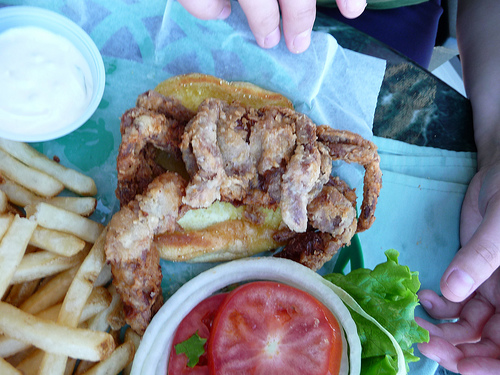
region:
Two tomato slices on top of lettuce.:
[168, 283, 345, 373]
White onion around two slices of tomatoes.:
[127, 255, 404, 372]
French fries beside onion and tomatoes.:
[0, 142, 116, 373]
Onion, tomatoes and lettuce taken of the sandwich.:
[129, 256, 431, 373]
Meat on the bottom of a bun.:
[107, 71, 383, 256]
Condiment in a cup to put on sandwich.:
[4, 38, 107, 144]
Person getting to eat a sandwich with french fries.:
[4, 2, 499, 373]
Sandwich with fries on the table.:
[0, 7, 491, 374]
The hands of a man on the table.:
[157, 0, 498, 372]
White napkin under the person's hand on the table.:
[357, 137, 472, 374]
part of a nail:
[450, 272, 470, 302]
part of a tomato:
[255, 332, 297, 369]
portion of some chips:
[18, 197, 73, 253]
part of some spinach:
[375, 302, 405, 332]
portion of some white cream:
[23, 70, 73, 120]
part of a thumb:
[461, 242, 486, 294]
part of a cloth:
[412, 170, 444, 210]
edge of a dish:
[82, 46, 107, 83]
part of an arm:
[460, 33, 490, 95]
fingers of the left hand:
[432, 310, 487, 362]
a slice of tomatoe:
[218, 287, 320, 372]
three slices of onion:
[97, 274, 377, 374]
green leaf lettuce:
[303, 245, 435, 373]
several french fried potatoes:
[0, 153, 123, 358]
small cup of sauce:
[8, 12, 114, 142]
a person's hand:
[406, 147, 498, 367]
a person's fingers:
[164, 4, 394, 54]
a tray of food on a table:
[53, 44, 476, 374]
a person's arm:
[430, 2, 497, 161]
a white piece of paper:
[145, 46, 407, 137]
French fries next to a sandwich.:
[15, 196, 103, 336]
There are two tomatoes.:
[192, 310, 329, 368]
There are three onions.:
[152, 296, 216, 349]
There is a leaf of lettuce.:
[350, 272, 435, 370]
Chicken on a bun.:
[130, 110, 365, 244]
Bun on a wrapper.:
[152, 49, 301, 115]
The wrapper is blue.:
[118, 20, 245, 79]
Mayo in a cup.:
[8, 1, 110, 131]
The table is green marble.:
[391, 68, 478, 150]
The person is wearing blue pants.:
[392, 10, 472, 66]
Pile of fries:
[1, 145, 125, 373]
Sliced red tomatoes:
[212, 282, 340, 372]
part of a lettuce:
[328, 252, 430, 372]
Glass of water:
[0, 7, 108, 145]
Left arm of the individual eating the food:
[411, 1, 496, 371]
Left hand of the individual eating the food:
[415, 160, 495, 370]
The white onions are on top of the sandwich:
[141, 257, 425, 371]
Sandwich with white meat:
[105, 71, 375, 323]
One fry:
[0, 304, 117, 359]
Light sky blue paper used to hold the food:
[0, 1, 381, 132]